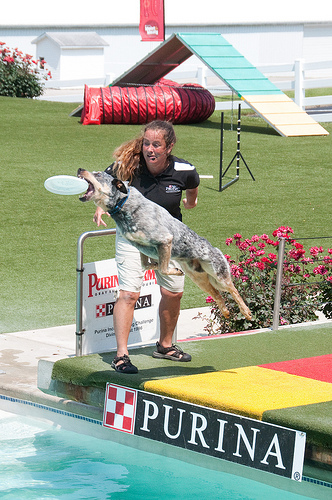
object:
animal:
[76, 167, 252, 320]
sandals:
[151, 342, 191, 362]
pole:
[270, 231, 286, 333]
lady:
[93, 121, 200, 370]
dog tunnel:
[82, 76, 215, 125]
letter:
[140, 398, 158, 436]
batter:
[43, 176, 91, 194]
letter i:
[213, 418, 226, 452]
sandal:
[111, 355, 138, 373]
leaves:
[289, 312, 299, 323]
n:
[234, 421, 259, 463]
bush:
[0, 35, 48, 98]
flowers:
[235, 233, 241, 242]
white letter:
[88, 273, 95, 295]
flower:
[225, 238, 234, 247]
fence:
[268, 235, 331, 331]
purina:
[104, 297, 150, 316]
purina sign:
[100, 378, 306, 481]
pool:
[3, 390, 329, 498]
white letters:
[145, 293, 154, 305]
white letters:
[162, 405, 184, 440]